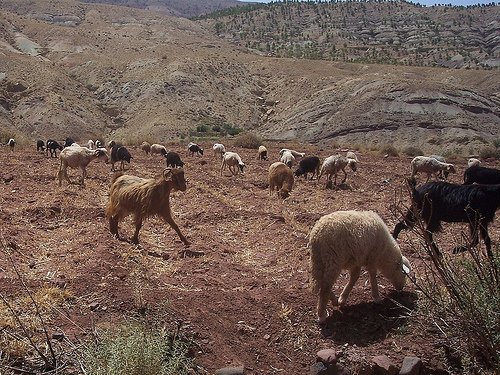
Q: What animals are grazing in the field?
A: Sheep.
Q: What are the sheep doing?
A: Grazing.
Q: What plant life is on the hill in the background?
A: Trees.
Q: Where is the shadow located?
A: Below the front white sheep.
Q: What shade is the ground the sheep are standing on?
A: Brown.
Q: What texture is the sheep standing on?
A: Dirt.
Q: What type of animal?
A: Sheep.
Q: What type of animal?
A: Sheep.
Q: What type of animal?
A: Sheep.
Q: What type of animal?
A: Sheep.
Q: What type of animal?
A: Sheep.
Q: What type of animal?
A: Sheep.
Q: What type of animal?
A: Sheep.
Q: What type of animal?
A: Sheep.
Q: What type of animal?
A: Sheep.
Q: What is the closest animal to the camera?
A: A sheep.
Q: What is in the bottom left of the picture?
A: A bush.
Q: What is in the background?
A: A hillside.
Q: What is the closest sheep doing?
A: Grazing.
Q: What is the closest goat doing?
A: Walking.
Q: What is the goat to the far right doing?
A: Walking.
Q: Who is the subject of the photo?
A: Animals.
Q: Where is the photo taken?
A: In the mountains.